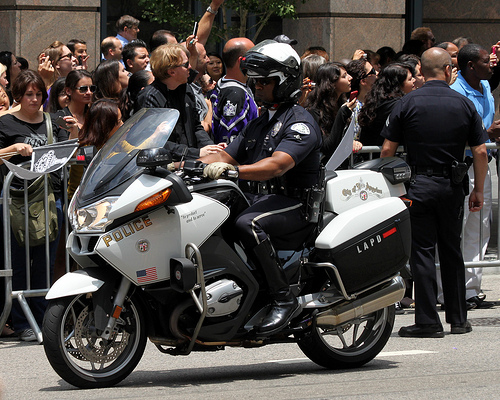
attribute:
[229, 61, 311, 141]
officer — standing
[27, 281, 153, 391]
front tire — small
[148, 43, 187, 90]
man — bald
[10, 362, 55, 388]
pavement — gray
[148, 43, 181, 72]
hair — blonde